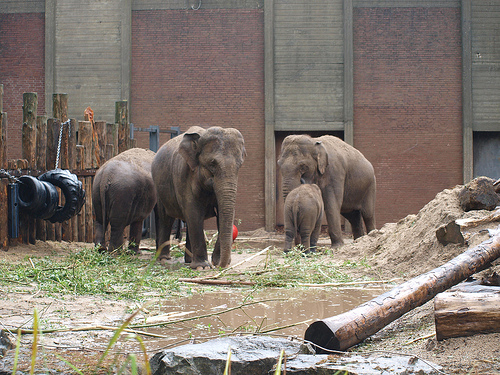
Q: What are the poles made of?
A: Wood.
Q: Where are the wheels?
A: On the left.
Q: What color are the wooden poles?
A: Brown.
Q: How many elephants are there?
A: 4.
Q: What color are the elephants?
A: Gray.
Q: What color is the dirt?
A: Brown.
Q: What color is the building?
A: Brown and gray.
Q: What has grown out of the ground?
A: Grass.